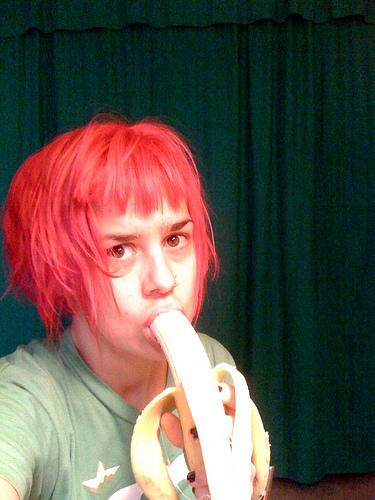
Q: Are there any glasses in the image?
A: No, there are no glasses.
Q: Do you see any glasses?
A: No, there are no glasses.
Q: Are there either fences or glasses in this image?
A: No, there are no glasses or fences.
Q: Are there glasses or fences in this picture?
A: No, there are no glasses or fences.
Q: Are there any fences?
A: No, there are no fences.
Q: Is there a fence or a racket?
A: No, there are no fences or rackets.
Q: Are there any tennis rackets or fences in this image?
A: No, there are no fences or tennis rackets.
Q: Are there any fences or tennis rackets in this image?
A: No, there are no fences or tennis rackets.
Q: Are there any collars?
A: Yes, there is a collar.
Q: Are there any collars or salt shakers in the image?
A: Yes, there is a collar.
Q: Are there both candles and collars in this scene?
A: No, there is a collar but no candles.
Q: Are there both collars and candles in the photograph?
A: No, there is a collar but no candles.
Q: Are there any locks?
A: No, there are no locks.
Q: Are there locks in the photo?
A: No, there are no locks.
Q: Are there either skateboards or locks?
A: No, there are no locks or skateboards.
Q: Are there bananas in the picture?
A: Yes, there is a banana.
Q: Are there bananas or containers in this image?
A: Yes, there is a banana.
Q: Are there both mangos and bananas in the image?
A: No, there is a banana but no mangoes.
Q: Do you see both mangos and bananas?
A: No, there is a banana but no mangoes.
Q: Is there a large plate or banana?
A: Yes, there is a large banana.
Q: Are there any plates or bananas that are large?
A: Yes, the banana is large.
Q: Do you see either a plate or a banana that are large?
A: Yes, the banana is large.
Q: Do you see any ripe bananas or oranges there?
A: Yes, there is a ripe banana.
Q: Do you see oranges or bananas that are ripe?
A: Yes, the banana is ripe.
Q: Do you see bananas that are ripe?
A: Yes, there is a ripe banana.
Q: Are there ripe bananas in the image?
A: Yes, there is a ripe banana.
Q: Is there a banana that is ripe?
A: Yes, there is a banana that is ripe.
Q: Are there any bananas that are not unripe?
A: Yes, there is an ripe banana.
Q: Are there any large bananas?
A: Yes, there is a large banana.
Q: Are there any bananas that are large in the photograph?
A: Yes, there is a large banana.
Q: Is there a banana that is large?
A: Yes, there is a banana that is large.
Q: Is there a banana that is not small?
A: Yes, there is a large banana.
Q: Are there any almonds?
A: No, there are no almonds.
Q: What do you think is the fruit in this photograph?
A: The fruit is a banana.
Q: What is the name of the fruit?
A: The fruit is a banana.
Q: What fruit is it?
A: The fruit is a banana.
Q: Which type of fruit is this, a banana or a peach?
A: This is a banana.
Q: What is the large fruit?
A: The fruit is a banana.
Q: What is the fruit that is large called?
A: The fruit is a banana.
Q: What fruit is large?
A: The fruit is a banana.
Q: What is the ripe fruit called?
A: The fruit is a banana.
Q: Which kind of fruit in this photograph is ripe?
A: The fruit is a banana.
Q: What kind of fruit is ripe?
A: The fruit is a banana.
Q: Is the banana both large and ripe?
A: Yes, the banana is large and ripe.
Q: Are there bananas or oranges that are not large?
A: No, there is a banana but it is large.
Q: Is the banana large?
A: Yes, the banana is large.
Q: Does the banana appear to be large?
A: Yes, the banana is large.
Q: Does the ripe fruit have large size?
A: Yes, the banana is large.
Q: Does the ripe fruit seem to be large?
A: Yes, the banana is large.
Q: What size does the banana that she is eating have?
A: The banana has large size.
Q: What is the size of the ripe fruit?
A: The banana is large.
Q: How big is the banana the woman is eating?
A: The banana is large.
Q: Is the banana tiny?
A: No, the banana is large.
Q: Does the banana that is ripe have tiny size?
A: No, the banana is large.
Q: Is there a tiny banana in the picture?
A: No, there is a banana but it is large.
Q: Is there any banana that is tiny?
A: No, there is a banana but it is large.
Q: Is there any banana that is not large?
A: No, there is a banana but it is large.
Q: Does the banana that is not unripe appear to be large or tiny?
A: The banana is large.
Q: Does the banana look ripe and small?
A: No, the banana is ripe but large.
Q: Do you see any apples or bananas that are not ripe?
A: No, there is a banana but it is ripe.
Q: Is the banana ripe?
A: Yes, the banana is ripe.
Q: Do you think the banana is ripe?
A: Yes, the banana is ripe.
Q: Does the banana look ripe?
A: Yes, the banana is ripe.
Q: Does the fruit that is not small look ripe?
A: Yes, the banana is ripe.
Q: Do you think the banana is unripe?
A: No, the banana is ripe.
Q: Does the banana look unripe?
A: No, the banana is ripe.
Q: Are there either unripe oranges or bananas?
A: No, there is a banana but it is ripe.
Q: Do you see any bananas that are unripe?
A: No, there is a banana but it is ripe.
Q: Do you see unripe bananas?
A: No, there is a banana but it is ripe.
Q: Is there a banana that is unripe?
A: No, there is a banana but it is ripe.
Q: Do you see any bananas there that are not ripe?
A: No, there is a banana but it is ripe.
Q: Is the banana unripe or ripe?
A: The banana is ripe.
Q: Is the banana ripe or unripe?
A: The banana is ripe.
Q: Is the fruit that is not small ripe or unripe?
A: The banana is ripe.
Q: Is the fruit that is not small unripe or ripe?
A: The banana is ripe.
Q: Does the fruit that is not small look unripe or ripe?
A: The banana is ripe.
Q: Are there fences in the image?
A: No, there are no fences.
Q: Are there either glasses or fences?
A: No, there are no fences or glasses.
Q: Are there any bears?
A: No, there are no bears.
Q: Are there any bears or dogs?
A: No, there are no bears or dogs.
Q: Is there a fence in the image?
A: No, there are no fences.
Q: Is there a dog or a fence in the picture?
A: No, there are no fences or dogs.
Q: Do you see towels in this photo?
A: No, there are no towels.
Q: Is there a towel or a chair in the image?
A: No, there are no towels or chairs.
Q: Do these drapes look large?
A: Yes, the drapes are large.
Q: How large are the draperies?
A: The draperies are large.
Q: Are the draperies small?
A: No, the draperies are large.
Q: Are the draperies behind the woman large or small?
A: The draperies are large.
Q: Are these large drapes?
A: Yes, these are large drapes.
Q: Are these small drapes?
A: No, these are large drapes.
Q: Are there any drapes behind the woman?
A: Yes, there are drapes behind the woman.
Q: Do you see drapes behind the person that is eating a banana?
A: Yes, there are drapes behind the woman.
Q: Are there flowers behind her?
A: No, there are drapes behind the woman.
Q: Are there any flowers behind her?
A: No, there are drapes behind the woman.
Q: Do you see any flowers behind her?
A: No, there are drapes behind the woman.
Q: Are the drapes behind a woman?
A: Yes, the drapes are behind a woman.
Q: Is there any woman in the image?
A: Yes, there is a woman.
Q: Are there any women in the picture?
A: Yes, there is a woman.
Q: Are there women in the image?
A: Yes, there is a woman.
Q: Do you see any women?
A: Yes, there is a woman.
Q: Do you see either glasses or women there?
A: Yes, there is a woman.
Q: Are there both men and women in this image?
A: No, there is a woman but no men.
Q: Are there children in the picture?
A: No, there are no children.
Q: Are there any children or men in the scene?
A: No, there are no children or men.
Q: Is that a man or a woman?
A: That is a woman.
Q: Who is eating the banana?
A: The woman is eating the banana.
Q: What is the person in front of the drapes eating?
A: The woman is eating a banana.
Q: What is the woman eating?
A: The woman is eating a banana.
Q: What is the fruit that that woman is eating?
A: The fruit is a banana.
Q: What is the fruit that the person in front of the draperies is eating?
A: The fruit is a banana.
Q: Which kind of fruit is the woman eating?
A: The woman is eating a banana.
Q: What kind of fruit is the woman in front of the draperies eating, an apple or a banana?
A: The woman is eating a banana.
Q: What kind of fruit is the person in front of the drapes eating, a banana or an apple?
A: The woman is eating a banana.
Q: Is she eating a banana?
A: Yes, the woman is eating a banana.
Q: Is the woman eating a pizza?
A: No, the woman is eating a banana.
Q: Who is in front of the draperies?
A: The woman is in front of the draperies.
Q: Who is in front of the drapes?
A: The woman is in front of the draperies.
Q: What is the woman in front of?
A: The woman is in front of the draperies.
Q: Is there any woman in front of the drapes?
A: Yes, there is a woman in front of the drapes.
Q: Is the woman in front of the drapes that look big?
A: Yes, the woman is in front of the drapes.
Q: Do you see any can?
A: No, there are no cans.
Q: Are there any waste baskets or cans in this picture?
A: No, there are no cans or waste baskets.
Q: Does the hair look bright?
A: Yes, the hair is bright.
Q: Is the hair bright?
A: Yes, the hair is bright.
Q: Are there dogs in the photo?
A: No, there are no dogs.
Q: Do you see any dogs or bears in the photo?
A: No, there are no dogs or bears.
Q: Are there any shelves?
A: No, there are no shelves.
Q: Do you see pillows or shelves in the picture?
A: No, there are no shelves or pillows.